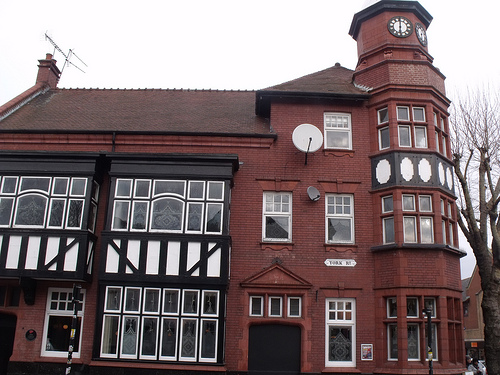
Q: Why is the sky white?
A: Cloudy.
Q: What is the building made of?
A: Red brick.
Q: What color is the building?
A: Red.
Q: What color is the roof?
A: Brown.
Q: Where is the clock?
A: Turret.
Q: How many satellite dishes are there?
A: Two.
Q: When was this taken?
A: During the day.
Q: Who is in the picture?
A: No one.